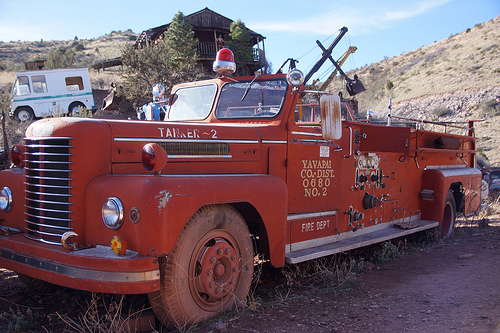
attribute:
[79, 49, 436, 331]
truck — red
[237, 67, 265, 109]
wipers — windshield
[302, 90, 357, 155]
mirror — rear-view, driver's side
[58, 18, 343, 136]
structure — wooden, distant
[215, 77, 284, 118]
windshield — driver's side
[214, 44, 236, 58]
light — red, strobe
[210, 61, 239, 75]
base — silver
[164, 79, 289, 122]
windshield — passenger side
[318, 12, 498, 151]
hillside — vegetation-free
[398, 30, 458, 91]
hillside — steep, vegetation-free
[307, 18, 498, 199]
hill — hilly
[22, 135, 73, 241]
radiator — meshed, metal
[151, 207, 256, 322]
tire — brown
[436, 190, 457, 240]
tire — brown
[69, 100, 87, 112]
tire — brown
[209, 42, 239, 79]
light — strobe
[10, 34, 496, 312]
truck — back of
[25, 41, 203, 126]
house — wooden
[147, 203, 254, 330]
wheel — large, reddish-colored, redish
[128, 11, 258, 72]
building — wooden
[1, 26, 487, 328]
fire truck — old style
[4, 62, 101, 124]
van — white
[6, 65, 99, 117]
truck — white